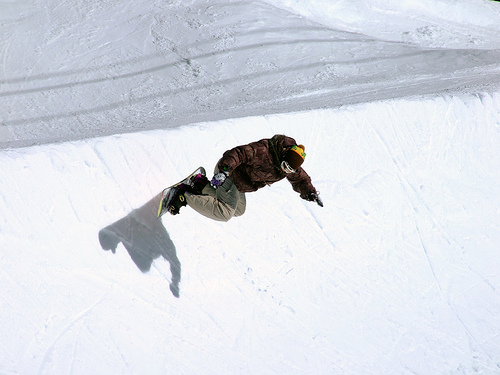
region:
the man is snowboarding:
[162, 128, 351, 293]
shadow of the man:
[90, 218, 195, 300]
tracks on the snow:
[106, 40, 383, 103]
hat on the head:
[272, 123, 302, 170]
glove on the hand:
[295, 188, 326, 210]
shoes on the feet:
[159, 186, 199, 211]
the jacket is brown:
[247, 153, 267, 180]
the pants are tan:
[197, 198, 229, 215]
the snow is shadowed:
[83, 48, 165, 93]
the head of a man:
[254, 130, 331, 192]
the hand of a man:
[286, 153, 353, 231]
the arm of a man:
[207, 128, 289, 185]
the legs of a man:
[156, 168, 259, 240]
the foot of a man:
[157, 168, 218, 226]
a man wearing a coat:
[200, 108, 330, 210]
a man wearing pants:
[157, 163, 257, 247]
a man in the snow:
[127, 108, 324, 260]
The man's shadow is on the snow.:
[96, 179, 188, 299]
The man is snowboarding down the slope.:
[153, 122, 325, 224]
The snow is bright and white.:
[2, 92, 498, 372]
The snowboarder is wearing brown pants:
[185, 171, 247, 221]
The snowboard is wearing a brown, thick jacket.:
[222, 135, 314, 203]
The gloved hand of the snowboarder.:
[207, 169, 228, 196]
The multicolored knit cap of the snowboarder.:
[280, 144, 306, 171]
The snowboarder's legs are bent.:
[187, 168, 249, 224]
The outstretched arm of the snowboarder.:
[284, 164, 324, 211]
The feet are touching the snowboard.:
[154, 166, 206, 221]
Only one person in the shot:
[93, 105, 370, 302]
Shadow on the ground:
[89, 168, 201, 308]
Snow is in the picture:
[235, 237, 398, 340]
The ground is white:
[270, 278, 436, 340]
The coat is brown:
[185, 108, 337, 223]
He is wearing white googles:
[275, 153, 295, 176]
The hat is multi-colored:
[286, 135, 311, 165]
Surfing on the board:
[145, 150, 211, 232]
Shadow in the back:
[40, 12, 406, 107]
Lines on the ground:
[47, 29, 437, 104]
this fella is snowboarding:
[122, 118, 324, 250]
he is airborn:
[145, 140, 337, 227]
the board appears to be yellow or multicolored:
[148, 158, 205, 228]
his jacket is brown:
[225, 136, 314, 212]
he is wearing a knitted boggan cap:
[256, 132, 309, 189]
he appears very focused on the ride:
[123, 137, 325, 246]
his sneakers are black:
[167, 182, 199, 224]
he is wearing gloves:
[207, 172, 230, 189]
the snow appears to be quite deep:
[244, 219, 426, 336]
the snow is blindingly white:
[276, 253, 442, 373]